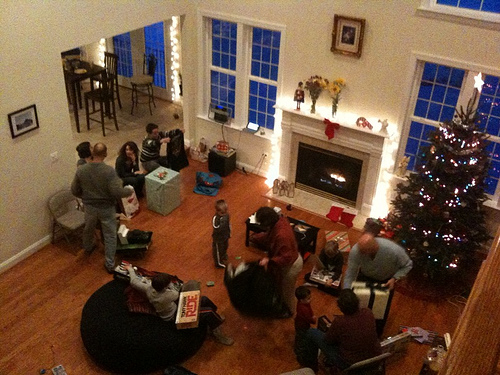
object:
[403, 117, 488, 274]
present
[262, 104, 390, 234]
fire place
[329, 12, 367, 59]
picture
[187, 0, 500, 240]
wall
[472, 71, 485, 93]
star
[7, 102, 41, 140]
picture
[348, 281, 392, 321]
present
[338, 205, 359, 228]
christmas stocking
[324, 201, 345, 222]
christmas stocking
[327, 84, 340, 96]
flowers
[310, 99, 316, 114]
vase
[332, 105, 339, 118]
vase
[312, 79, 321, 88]
flowers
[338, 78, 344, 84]
flowers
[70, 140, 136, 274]
adults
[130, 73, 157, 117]
chair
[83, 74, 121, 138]
chair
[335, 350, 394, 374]
chair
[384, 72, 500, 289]
christmas tree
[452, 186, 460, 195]
lights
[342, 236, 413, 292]
gray sweater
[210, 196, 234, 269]
toddler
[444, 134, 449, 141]
lights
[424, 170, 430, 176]
lights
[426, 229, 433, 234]
lights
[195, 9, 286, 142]
window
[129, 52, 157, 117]
room set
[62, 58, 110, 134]
room set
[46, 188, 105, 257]
chair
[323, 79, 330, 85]
flowers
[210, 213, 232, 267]
pajamas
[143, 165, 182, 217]
box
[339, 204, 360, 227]
stockings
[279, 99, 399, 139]
mantle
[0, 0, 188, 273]
wall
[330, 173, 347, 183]
fire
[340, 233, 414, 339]
man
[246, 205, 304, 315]
woman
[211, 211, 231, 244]
sweatshirt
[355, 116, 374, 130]
nutcracker